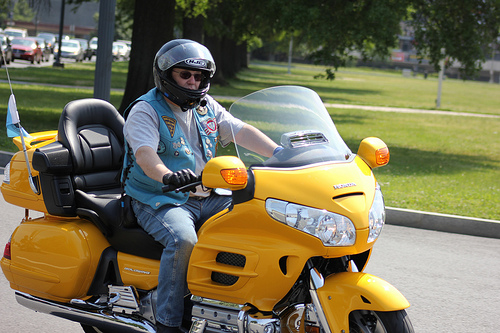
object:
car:
[7, 35, 46, 65]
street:
[3, 25, 93, 71]